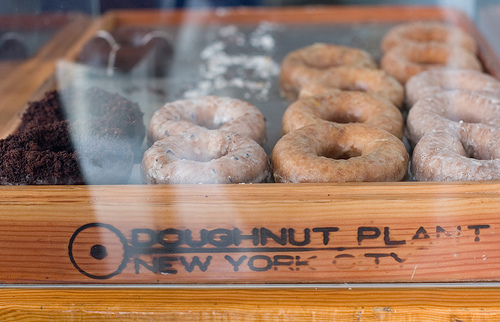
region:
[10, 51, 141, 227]
Chocolate donuts on display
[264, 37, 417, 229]
Glazed donuts on display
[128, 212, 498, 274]
This says Doughnut plant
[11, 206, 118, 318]
The wood is brown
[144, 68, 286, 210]
White glazed donuts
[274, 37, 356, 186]
The donuts are round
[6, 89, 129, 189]
The donut is brown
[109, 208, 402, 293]
The writing is black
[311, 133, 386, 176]
The donut has a hole in it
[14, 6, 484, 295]
The case is square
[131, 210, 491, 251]
black writing on the wood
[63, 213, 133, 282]
a logo on the wood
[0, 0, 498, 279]
a brown wooden box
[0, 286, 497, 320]
a brown wooden counter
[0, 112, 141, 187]
a dark brown donut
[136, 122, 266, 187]
a white glazed donut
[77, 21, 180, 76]
a chocolate glazed donut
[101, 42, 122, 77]
white frosting on the chocolate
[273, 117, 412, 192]
a brown glazed donut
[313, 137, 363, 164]
the middle of a donut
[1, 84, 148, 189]
The two chocolate donuts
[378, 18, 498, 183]
The longest line of donuts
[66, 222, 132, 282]
The donut seared onto the wood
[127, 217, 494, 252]
The name of the donut maker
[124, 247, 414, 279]
The city the donuts were made in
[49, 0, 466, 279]
The reflection in the glass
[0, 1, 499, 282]
The glass in front of the donuts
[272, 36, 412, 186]
The row of four donuts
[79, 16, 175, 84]
The chocolate donut with white piping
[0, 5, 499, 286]
The wood rack holding the donuts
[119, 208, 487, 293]
sign says doughnut plant new york city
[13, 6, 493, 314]
doughnuts are in a display case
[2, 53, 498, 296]
4 different types of doughnuts are in case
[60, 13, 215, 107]
doughnut is chocolate with white icing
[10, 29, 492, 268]
case is made of wood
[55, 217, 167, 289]
circle with dot is next to lettering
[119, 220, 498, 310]
the lettering is black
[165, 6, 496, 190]
the doughnuts are round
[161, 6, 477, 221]
the doughnuts have holes in them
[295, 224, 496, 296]
the black letters are fading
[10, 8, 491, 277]
there are fourteen donuts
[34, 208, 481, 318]
the city is new york city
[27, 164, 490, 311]
the place is called doughnut plant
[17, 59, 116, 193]
two chocolate sprinkle donuts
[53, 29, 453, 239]
the tray is wooden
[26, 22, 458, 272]
these donuts are under glass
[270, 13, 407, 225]
four glazed donuts in a row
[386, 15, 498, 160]
two glazed and three sugar donuts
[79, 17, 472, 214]
donuts behind the counter